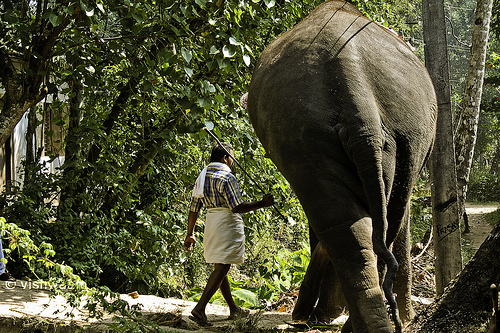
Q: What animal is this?
A: An elephant.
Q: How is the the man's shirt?
A: Blue checked.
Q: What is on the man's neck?
A: A white scarf.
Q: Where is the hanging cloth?
A: Between the trees.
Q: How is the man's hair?
A: Short and dark.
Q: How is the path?
A: Grey and rocky.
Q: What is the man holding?
A: A stick.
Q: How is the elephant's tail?
A: Long and thick.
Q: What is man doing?
A: Walking with elephant.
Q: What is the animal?
A: Elephant.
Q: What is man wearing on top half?
A: Shirt.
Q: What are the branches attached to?
A: Tree.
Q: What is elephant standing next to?
A: Man with dark hair.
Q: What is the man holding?
A: Stick.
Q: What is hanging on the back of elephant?
A: Tail.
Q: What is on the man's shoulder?
A: Towel.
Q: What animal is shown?
A: Elephant.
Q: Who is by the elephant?
A: A person.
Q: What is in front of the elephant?
A: Trees.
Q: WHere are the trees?
A: In front of the elephant.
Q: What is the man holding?
A: A stick.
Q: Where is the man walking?
A: By the elephant.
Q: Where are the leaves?
A: On the trees.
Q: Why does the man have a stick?
A: For the elephant.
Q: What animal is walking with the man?
A: Elephant.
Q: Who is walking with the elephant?
A: The man.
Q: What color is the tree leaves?
A: Green.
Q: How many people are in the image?
A: 1.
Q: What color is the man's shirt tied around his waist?
A: White.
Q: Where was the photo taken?
A: In the forest.